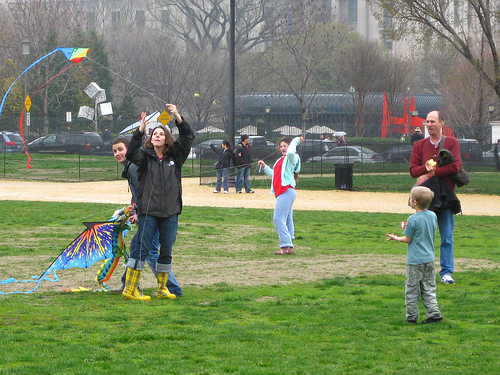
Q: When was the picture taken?
A: Daytime.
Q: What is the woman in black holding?
A: Kite.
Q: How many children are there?
A: One.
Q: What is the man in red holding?
A: Jacket.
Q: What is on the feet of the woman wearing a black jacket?
A: Rain boots.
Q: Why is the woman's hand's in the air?
A: She is flying a kite.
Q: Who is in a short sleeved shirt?
A: A kid.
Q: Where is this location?
A: Park.